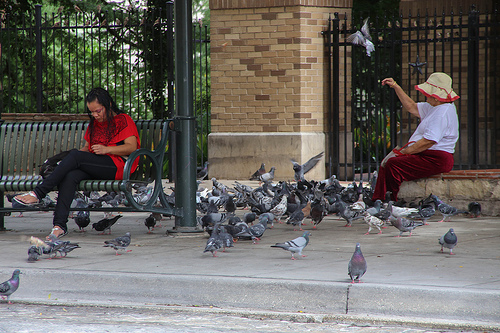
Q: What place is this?
A: It is a sidewalk.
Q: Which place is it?
A: It is a sidewalk.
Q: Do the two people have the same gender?
A: Yes, all the people are female.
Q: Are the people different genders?
A: No, all the people are female.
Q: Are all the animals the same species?
A: Yes, all the animals are birds.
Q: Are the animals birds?
A: Yes, all the animals are birds.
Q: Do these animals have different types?
A: No, all the animals are birds.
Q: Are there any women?
A: Yes, there is a woman.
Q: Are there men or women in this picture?
A: Yes, there is a woman.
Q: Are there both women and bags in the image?
A: No, there is a woman but no bags.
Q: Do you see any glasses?
A: No, there are no glasses.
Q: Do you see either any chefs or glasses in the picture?
A: No, there are no glasses or chefs.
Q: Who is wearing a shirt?
A: The woman is wearing a shirt.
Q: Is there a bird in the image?
A: Yes, there is a bird.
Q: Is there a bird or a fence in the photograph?
A: Yes, there is a bird.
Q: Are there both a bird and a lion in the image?
A: No, there is a bird but no lions.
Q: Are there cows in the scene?
A: No, there are no cows.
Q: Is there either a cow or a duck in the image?
A: No, there are no cows or ducks.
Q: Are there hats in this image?
A: Yes, there is a hat.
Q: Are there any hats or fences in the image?
A: Yes, there is a hat.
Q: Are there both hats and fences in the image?
A: Yes, there are both a hat and a fence.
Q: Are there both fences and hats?
A: Yes, there are both a hat and a fence.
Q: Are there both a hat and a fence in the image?
A: Yes, there are both a hat and a fence.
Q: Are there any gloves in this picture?
A: No, there are no gloves.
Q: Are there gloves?
A: No, there are no gloves.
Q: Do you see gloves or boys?
A: No, there are no gloves or boys.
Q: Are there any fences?
A: Yes, there is a fence.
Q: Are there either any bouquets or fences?
A: Yes, there is a fence.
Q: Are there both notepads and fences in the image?
A: No, there is a fence but no notepads.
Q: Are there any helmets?
A: No, there are no helmets.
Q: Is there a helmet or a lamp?
A: No, there are no helmets or lamps.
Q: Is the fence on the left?
A: Yes, the fence is on the left of the image.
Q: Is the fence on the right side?
A: No, the fence is on the left of the image.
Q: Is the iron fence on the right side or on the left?
A: The fence is on the left of the image.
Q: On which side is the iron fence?
A: The fence is on the left of the image.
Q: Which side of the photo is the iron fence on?
A: The fence is on the left of the image.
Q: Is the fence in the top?
A: Yes, the fence is in the top of the image.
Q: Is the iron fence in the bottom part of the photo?
A: No, the fence is in the top of the image.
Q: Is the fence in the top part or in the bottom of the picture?
A: The fence is in the top of the image.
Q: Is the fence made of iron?
A: Yes, the fence is made of iron.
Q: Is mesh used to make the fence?
A: No, the fence is made of iron.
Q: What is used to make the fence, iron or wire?
A: The fence is made of iron.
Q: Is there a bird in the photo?
A: Yes, there is a bird.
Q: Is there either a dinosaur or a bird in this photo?
A: Yes, there is a bird.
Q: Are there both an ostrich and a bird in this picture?
A: No, there is a bird but no ostriches.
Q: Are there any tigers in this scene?
A: No, there are no tigers.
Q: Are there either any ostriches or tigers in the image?
A: No, there are no tigers or ostriches.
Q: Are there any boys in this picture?
A: No, there are no boys.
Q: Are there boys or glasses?
A: No, there are no boys or glasses.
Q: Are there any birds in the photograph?
A: Yes, there is a bird.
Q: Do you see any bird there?
A: Yes, there is a bird.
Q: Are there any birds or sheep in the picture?
A: Yes, there is a bird.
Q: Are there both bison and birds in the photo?
A: No, there is a bird but no bison.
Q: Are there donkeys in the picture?
A: No, there are no donkeys.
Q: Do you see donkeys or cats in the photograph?
A: No, there are no donkeys or cats.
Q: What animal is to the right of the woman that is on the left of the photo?
A: The animal is a bird.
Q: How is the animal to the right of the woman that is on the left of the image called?
A: The animal is a bird.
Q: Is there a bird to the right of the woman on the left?
A: Yes, there is a bird to the right of the woman.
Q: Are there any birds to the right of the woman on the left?
A: Yes, there is a bird to the right of the woman.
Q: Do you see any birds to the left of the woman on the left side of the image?
A: No, the bird is to the right of the woman.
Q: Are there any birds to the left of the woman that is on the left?
A: No, the bird is to the right of the woman.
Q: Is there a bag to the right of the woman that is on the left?
A: No, there is a bird to the right of the woman.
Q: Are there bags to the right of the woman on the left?
A: No, there is a bird to the right of the woman.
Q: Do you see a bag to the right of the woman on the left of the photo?
A: No, there is a bird to the right of the woman.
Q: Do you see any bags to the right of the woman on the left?
A: No, there is a bird to the right of the woman.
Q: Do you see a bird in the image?
A: Yes, there is a bird.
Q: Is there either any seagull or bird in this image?
A: Yes, there is a bird.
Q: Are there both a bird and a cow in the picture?
A: No, there is a bird but no cows.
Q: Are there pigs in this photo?
A: No, there are no pigs.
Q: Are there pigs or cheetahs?
A: No, there are no pigs or cheetahs.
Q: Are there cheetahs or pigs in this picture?
A: No, there are no pigs or cheetahs.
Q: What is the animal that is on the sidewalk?
A: The animal is a bird.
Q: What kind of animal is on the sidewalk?
A: The animal is a bird.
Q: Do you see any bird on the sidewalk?
A: Yes, there is a bird on the sidewalk.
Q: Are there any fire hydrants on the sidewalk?
A: No, there is a bird on the sidewalk.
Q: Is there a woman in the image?
A: Yes, there is a woman.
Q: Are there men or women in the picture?
A: Yes, there is a woman.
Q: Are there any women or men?
A: Yes, there is a woman.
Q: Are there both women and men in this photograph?
A: No, there is a woman but no men.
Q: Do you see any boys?
A: No, there are no boys.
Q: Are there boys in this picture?
A: No, there are no boys.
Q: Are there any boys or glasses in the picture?
A: No, there are no boys or glasses.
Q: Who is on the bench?
A: The woman is on the bench.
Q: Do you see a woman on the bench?
A: Yes, there is a woman on the bench.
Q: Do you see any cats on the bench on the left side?
A: No, there is a woman on the bench.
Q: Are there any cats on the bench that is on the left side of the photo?
A: No, there is a woman on the bench.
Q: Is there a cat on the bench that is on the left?
A: No, there is a woman on the bench.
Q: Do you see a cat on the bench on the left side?
A: No, there is a woman on the bench.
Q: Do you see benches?
A: Yes, there is a bench.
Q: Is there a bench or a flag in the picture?
A: Yes, there is a bench.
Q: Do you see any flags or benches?
A: Yes, there is a bench.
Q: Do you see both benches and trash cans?
A: No, there is a bench but no trash cans.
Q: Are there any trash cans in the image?
A: No, there are no trash cans.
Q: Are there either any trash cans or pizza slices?
A: No, there are no trash cans or pizza slices.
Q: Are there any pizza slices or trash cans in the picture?
A: No, there are no trash cans or pizza slices.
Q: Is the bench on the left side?
A: Yes, the bench is on the left of the image.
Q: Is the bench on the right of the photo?
A: No, the bench is on the left of the image.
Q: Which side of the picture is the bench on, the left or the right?
A: The bench is on the left of the image.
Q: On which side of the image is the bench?
A: The bench is on the left of the image.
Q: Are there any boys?
A: No, there are no boys.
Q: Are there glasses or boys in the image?
A: No, there are no boys or glasses.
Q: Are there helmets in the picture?
A: No, there are no helmets.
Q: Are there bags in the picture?
A: No, there are no bags.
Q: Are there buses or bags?
A: No, there are no bags or buses.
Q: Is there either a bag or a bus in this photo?
A: No, there are no bags or buses.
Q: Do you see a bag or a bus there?
A: No, there are no bags or buses.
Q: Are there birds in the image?
A: Yes, there is a bird.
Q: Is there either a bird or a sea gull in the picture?
A: Yes, there is a bird.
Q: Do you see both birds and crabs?
A: No, there is a bird but no crabs.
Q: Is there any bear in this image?
A: No, there are no bears.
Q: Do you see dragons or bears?
A: No, there are no bears or dragons.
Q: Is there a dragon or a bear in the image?
A: No, there are no bears or dragons.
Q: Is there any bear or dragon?
A: No, there are no bears or dragons.